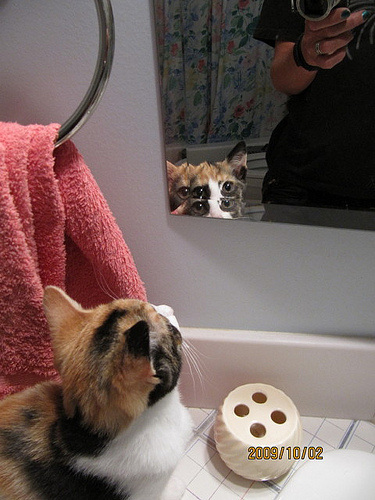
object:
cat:
[0, 285, 210, 500]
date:
[248, 446, 324, 460]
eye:
[222, 179, 235, 194]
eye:
[191, 184, 208, 199]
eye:
[176, 185, 192, 201]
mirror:
[149, 0, 375, 232]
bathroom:
[0, 0, 375, 499]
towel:
[0, 119, 148, 402]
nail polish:
[341, 9, 351, 19]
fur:
[30, 412, 66, 453]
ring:
[315, 43, 324, 56]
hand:
[293, 7, 369, 96]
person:
[251, 0, 375, 215]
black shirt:
[260, 43, 374, 213]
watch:
[292, 35, 322, 72]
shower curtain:
[152, 0, 291, 146]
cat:
[166, 140, 248, 220]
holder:
[212, 382, 302, 481]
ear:
[123, 319, 160, 361]